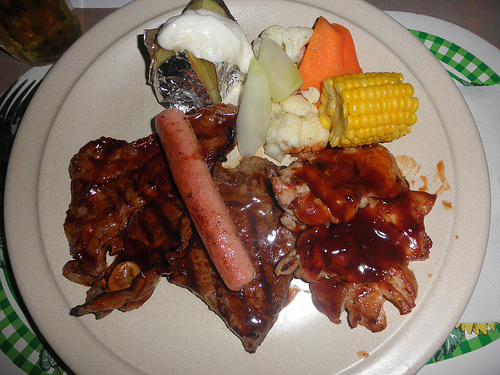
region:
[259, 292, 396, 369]
the plate is white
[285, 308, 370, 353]
the plate is white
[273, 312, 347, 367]
the plate is white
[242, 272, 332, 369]
the plate is white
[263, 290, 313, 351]
the plate is white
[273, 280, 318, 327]
the plate is white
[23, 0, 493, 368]
a plate of food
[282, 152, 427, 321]
barbecued pulled meat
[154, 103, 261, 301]
a hot dog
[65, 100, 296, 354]
grilled barbecued meat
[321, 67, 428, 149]
a small corn on the cob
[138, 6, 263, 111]
a tiny baked potato with sour cream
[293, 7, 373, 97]
what appears to be carrots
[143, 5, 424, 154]
a bunch of different vegetables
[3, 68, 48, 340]
a fork to eat this deliciousness with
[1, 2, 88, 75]
a drink to wash it all down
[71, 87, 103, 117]
this is a plate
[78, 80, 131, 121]
the plate is white in color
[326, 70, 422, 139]
this is some maize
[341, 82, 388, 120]
the maize is yellow in color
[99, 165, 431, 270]
this is some beef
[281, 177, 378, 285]
the beef is oily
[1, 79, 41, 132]
this is a fork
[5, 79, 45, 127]
the fork is metallic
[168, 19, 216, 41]
the substance is white in color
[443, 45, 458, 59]
the mat is white and green in color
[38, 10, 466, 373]
a white plate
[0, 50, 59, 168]
A silver fork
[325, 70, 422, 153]
some corn on the plate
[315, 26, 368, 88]
some carrots on the plate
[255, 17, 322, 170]
some cauliflower on the plate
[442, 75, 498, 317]
a paper towel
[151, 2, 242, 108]
some aluminum foil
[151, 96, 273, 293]
a hot dog on top of the chicken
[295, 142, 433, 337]
some pulled barbecue meat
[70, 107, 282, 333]
some pieces of barbecue chicken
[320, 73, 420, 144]
Mini cob of corn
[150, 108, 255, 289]
Pink hot dog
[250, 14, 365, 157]
Pieces of white cauliflower and carrots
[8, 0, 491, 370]
Beige circular plate of food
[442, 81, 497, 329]
Simple white napkin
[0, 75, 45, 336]
Metal fork with four tines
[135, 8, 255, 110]
Foil-wrapped baked potato with sour cream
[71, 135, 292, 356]
Grilled steak with sauce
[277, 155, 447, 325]
Grilled chicken with sauce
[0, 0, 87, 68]
Bottom of beverage glass